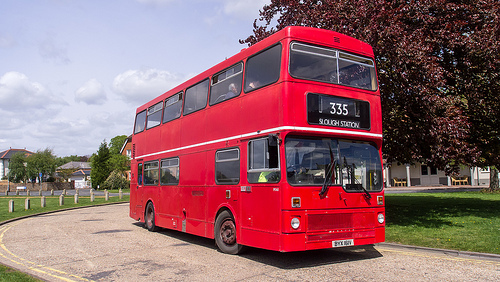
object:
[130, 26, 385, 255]
bus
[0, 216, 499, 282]
street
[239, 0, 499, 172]
tree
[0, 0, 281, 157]
sky